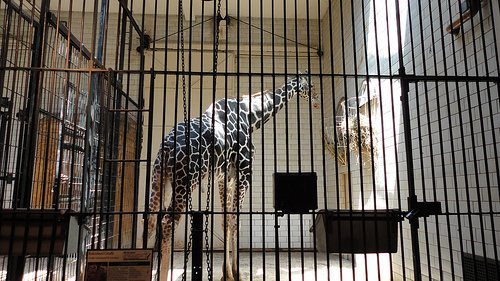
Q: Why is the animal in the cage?
A: To stop from trying to leave.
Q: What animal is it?
A: A giraffe.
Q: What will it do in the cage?
A: Eat and look around.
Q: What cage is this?
A: A long and tall metal one.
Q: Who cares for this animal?
A: Zookeepers.